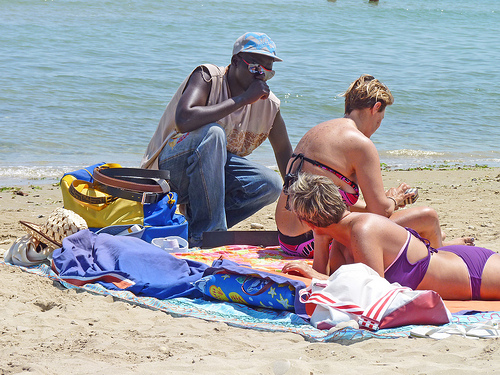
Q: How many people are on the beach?
A: Three.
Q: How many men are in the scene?
A: One.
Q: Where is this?
A: Beach.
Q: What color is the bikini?
A: Purple.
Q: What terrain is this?
A: Sand.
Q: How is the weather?
A: Sunny.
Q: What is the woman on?
A: Towel.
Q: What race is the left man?
A: Black.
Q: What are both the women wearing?
A: Bikinis.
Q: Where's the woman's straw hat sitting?
A: On the blanket.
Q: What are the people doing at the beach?
A: Hanging out.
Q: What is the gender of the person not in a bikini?
A: Male.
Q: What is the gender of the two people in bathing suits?
A: Female.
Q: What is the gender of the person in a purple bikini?
A: Female.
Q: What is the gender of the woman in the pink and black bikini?
A: Female.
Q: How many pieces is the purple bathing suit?
A: Two.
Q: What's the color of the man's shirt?
A: Brown.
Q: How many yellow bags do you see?
A: One.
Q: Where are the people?
A: At the beach.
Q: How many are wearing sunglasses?
A: One.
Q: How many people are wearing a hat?
A: One.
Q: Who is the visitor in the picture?
A: The man in jeans.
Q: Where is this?
A: Cancun or other beach.